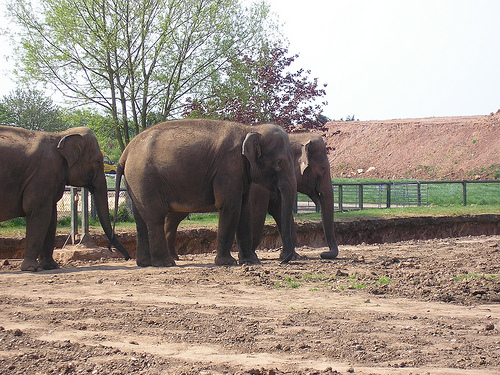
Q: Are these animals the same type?
A: Yes, all the animals are elephants.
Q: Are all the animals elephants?
A: Yes, all the animals are elephants.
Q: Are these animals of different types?
A: No, all the animals are elephants.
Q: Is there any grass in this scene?
A: Yes, there is grass.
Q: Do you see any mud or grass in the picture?
A: Yes, there is grass.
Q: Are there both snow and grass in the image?
A: No, there is grass but no snow.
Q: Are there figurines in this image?
A: No, there are no figurines.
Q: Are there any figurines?
A: No, there are no figurines.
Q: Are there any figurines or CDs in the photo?
A: No, there are no figurines or cds.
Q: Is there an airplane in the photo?
A: No, there are no airplanes.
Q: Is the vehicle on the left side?
A: Yes, the vehicle is on the left of the image.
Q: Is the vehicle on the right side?
A: No, the vehicle is on the left of the image.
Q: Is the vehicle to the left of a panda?
A: No, the vehicle is to the left of an elephant.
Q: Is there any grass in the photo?
A: Yes, there is grass.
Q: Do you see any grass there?
A: Yes, there is grass.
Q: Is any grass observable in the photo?
A: Yes, there is grass.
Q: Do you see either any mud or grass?
A: Yes, there is grass.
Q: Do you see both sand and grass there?
A: No, there is grass but no sand.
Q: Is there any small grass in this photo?
A: Yes, there is small grass.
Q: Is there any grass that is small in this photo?
A: Yes, there is small grass.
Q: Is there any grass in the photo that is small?
A: Yes, there is small grass.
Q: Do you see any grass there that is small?
A: Yes, there is grass that is small.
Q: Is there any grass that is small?
A: Yes, there is grass that is small.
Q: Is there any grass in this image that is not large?
A: Yes, there is small grass.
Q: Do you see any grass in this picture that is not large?
A: Yes, there is small grass.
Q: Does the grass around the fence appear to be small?
A: Yes, the grass is small.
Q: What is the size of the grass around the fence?
A: The grass is small.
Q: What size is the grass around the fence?
A: The grass is small.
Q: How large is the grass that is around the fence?
A: The grass is small.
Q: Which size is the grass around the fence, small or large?
A: The grass is small.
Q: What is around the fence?
A: The grass is around the fence.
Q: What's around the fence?
A: The grass is around the fence.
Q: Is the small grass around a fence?
A: Yes, the grass is around a fence.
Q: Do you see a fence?
A: Yes, there is a fence.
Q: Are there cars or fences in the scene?
A: Yes, there is a fence.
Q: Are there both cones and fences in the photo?
A: No, there is a fence but no cones.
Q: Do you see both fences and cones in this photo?
A: No, there is a fence but no cones.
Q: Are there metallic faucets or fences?
A: Yes, there is a metal fence.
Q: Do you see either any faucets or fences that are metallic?
A: Yes, the fence is metallic.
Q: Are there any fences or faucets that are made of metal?
A: Yes, the fence is made of metal.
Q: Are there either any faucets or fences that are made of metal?
A: Yes, the fence is made of metal.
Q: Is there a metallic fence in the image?
A: Yes, there is a metal fence.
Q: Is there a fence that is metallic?
A: Yes, there is a fence that is metallic.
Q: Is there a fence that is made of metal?
A: Yes, there is a fence that is made of metal.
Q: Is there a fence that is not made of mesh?
A: Yes, there is a fence that is made of metal.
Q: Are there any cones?
A: No, there are no cones.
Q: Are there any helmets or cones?
A: No, there are no cones or helmets.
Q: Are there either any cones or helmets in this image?
A: No, there are no cones or helmets.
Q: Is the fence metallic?
A: Yes, the fence is metallic.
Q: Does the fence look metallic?
A: Yes, the fence is metallic.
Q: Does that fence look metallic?
A: Yes, the fence is metallic.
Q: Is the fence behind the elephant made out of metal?
A: Yes, the fence is made of metal.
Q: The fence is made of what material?
A: The fence is made of metal.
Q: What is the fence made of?
A: The fence is made of metal.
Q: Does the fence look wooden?
A: No, the fence is metallic.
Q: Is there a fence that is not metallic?
A: No, there is a fence but it is metallic.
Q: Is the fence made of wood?
A: No, the fence is made of metal.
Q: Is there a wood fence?
A: No, there is a fence but it is made of metal.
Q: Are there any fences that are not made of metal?
A: No, there is a fence but it is made of metal.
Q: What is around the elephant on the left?
A: The fence is around the elephant.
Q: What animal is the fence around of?
A: The fence is around the elephant.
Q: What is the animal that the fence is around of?
A: The animal is an elephant.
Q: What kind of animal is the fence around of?
A: The fence is around the elephant.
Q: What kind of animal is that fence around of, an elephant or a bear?
A: The fence is around an elephant.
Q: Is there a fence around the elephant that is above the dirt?
A: Yes, there is a fence around the elephant.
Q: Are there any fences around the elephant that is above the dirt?
A: Yes, there is a fence around the elephant.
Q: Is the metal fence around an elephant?
A: Yes, the fence is around an elephant.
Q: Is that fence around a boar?
A: No, the fence is around an elephant.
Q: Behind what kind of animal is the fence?
A: The fence is behind the elephant.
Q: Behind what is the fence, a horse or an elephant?
A: The fence is behind an elephant.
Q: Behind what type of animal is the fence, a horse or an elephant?
A: The fence is behind an elephant.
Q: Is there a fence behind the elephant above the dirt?
A: Yes, there is a fence behind the elephant.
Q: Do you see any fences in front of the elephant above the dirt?
A: No, the fence is behind the elephant.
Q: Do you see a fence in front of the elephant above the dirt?
A: No, the fence is behind the elephant.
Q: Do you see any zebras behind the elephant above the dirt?
A: No, there is a fence behind the elephant.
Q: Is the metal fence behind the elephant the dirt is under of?
A: Yes, the fence is behind the elephant.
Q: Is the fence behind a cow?
A: No, the fence is behind the elephant.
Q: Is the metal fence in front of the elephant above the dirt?
A: No, the fence is behind the elephant.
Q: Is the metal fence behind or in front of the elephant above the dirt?
A: The fence is behind the elephant.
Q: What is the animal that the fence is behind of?
A: The animal is an elephant.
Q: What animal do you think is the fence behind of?
A: The fence is behind the elephant.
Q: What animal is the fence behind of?
A: The fence is behind the elephant.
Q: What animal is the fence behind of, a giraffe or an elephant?
A: The fence is behind an elephant.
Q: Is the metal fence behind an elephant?
A: Yes, the fence is behind an elephant.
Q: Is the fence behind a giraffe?
A: No, the fence is behind an elephant.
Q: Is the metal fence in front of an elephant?
A: No, the fence is behind an elephant.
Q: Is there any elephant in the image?
A: Yes, there is an elephant.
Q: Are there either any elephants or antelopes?
A: Yes, there is an elephant.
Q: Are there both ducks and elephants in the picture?
A: No, there is an elephant but no ducks.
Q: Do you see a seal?
A: No, there are no seals.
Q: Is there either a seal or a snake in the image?
A: No, there are no seals or snakes.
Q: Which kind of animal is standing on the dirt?
A: The animal is an elephant.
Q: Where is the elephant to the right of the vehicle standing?
A: The elephant is standing on the dirt.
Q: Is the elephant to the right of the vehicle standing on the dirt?
A: Yes, the elephant is standing on the dirt.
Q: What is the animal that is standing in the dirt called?
A: The animal is an elephant.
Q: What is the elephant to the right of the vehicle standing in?
A: The elephant is standing in the dirt.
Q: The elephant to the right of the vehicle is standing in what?
A: The elephant is standing in the dirt.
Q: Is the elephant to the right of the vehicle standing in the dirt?
A: Yes, the elephant is standing in the dirt.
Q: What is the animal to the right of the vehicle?
A: The animal is an elephant.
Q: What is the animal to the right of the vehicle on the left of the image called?
A: The animal is an elephant.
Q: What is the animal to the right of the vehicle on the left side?
A: The animal is an elephant.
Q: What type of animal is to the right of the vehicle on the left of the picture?
A: The animal is an elephant.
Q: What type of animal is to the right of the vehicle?
A: The animal is an elephant.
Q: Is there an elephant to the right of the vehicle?
A: Yes, there is an elephant to the right of the vehicle.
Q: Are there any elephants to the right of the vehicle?
A: Yes, there is an elephant to the right of the vehicle.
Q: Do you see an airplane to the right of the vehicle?
A: No, there is an elephant to the right of the vehicle.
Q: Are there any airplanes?
A: No, there are no airplanes.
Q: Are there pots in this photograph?
A: No, there are no pots.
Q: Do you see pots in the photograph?
A: No, there are no pots.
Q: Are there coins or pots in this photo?
A: No, there are no pots or coins.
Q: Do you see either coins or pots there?
A: No, there are no pots or coins.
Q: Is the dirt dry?
A: Yes, the dirt is dry.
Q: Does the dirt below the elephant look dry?
A: Yes, the dirt is dry.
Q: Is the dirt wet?
A: No, the dirt is dry.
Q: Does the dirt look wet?
A: No, the dirt is dry.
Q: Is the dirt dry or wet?
A: The dirt is dry.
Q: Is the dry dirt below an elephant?
A: Yes, the dirt is below an elephant.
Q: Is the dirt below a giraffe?
A: No, the dirt is below an elephant.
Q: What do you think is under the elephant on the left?
A: The dirt is under the elephant.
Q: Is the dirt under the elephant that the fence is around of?
A: Yes, the dirt is under the elephant.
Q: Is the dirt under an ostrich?
A: No, the dirt is under the elephant.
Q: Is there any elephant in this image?
A: Yes, there is an elephant.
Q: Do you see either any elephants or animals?
A: Yes, there is an elephant.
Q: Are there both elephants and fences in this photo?
A: Yes, there are both an elephant and a fence.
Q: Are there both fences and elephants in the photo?
A: Yes, there are both an elephant and a fence.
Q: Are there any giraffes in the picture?
A: No, there are no giraffes.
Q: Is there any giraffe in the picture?
A: No, there are no giraffes.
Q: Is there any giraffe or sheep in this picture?
A: No, there are no giraffes or sheep.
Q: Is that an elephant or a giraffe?
A: That is an elephant.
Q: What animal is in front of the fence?
A: The elephant is in front of the fence.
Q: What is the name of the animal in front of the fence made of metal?
A: The animal is an elephant.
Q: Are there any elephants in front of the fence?
A: Yes, there is an elephant in front of the fence.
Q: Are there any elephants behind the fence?
A: No, the elephant is in front of the fence.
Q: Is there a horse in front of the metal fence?
A: No, there is an elephant in front of the fence.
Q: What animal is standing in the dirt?
A: The elephant is standing in the dirt.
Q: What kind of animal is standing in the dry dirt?
A: The animal is an elephant.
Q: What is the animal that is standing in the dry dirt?
A: The animal is an elephant.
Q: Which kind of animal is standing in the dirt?
A: The animal is an elephant.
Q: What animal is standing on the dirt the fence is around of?
A: The elephant is standing on the dirt.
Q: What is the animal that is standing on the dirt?
A: The animal is an elephant.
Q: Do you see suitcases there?
A: No, there are no suitcases.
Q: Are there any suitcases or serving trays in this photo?
A: No, there are no suitcases or serving trays.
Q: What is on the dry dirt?
A: The trunk is on the dirt.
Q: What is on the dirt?
A: The trunk is on the dirt.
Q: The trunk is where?
A: The trunk is on the dirt.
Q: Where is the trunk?
A: The trunk is on the dirt.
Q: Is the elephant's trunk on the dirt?
A: Yes, the trunk is on the dirt.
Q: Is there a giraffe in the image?
A: No, there are no giraffes.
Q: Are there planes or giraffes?
A: No, there are no giraffes or planes.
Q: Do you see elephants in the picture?
A: Yes, there is an elephant.